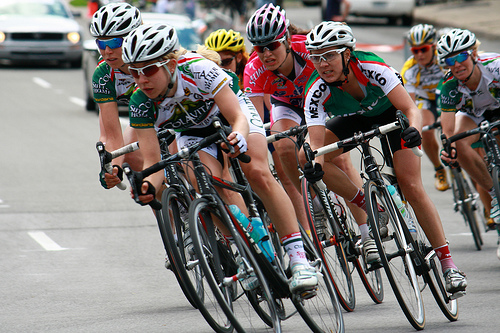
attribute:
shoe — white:
[439, 265, 469, 293]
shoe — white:
[361, 203, 391, 239]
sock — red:
[431, 242, 461, 276]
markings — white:
[28, 74, 91, 109]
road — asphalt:
[2, 6, 496, 331]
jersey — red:
[237, 33, 318, 108]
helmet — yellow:
[197, 25, 249, 58]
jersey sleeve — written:
[301, 65, 338, 130]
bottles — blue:
[233, 199, 289, 274]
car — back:
[322, 0, 417, 21]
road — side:
[350, 21, 410, 44]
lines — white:
[27, 70, 114, 127]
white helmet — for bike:
[89, 2, 141, 36]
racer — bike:
[301, 20, 462, 330]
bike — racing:
[317, 101, 417, 323]